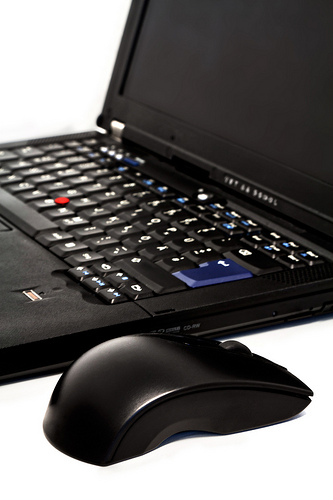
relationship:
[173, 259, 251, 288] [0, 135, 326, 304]
button on key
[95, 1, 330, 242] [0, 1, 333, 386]
monitor of laptop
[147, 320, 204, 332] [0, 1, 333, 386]
writing on side of laptop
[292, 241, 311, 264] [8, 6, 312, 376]
button on laptop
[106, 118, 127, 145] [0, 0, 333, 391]
hinges on computer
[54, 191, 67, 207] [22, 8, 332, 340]
pointing stick on thinkpad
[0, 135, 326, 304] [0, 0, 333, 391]
key on computer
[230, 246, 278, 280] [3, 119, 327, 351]
backspace key on keyboard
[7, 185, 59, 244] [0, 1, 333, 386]
spacebar on laptop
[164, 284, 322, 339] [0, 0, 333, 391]
drive on side of computer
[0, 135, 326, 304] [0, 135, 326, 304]
key on key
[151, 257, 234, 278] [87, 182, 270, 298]
key on keyboard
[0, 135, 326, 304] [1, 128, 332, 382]
key on keyboard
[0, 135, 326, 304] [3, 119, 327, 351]
key on keyboard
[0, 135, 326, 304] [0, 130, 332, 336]
key on keyboard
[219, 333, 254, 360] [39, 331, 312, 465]
mouse wheel on black mouse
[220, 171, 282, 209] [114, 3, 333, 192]
company name on monitor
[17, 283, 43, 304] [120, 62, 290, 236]
print scanner on laptop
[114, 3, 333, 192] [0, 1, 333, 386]
monitor on laptop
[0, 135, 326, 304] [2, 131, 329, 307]
key on keyboard